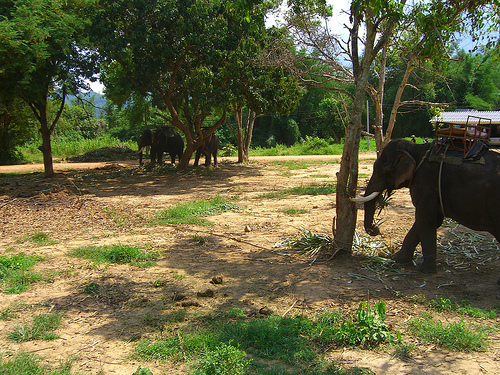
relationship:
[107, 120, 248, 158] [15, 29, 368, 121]
elephants under trees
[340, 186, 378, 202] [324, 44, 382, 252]
tusks near tree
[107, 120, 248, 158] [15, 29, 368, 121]
elephants near trees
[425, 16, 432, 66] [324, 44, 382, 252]
leaves on tree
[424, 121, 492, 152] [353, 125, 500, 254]
bench on elephant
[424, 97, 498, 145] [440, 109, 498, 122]
building has roof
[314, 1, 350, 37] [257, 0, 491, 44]
clouds in sky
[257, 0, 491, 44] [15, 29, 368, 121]
sky through trees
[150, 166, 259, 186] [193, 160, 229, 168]
shade under feet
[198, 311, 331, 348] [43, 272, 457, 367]
grass on ground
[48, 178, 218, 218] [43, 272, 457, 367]
dirt on ground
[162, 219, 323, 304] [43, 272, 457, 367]
shadow on ground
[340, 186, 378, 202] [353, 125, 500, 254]
tusks on elephant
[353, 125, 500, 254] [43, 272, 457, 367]
elephant on ground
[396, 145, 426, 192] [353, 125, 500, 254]
ear of elephant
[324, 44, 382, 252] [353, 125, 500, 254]
tree by elephant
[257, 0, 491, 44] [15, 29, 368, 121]
sky above trees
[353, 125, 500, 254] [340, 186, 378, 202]
elephant has tusks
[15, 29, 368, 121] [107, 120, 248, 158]
trees and elephants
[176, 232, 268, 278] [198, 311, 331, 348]
sand on grass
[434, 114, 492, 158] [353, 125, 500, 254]
bench on elephant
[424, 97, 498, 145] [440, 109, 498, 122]
barn with roof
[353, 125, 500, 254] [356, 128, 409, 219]
elephant has head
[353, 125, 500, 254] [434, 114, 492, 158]
elephant wearing bench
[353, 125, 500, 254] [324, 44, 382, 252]
elephant by tree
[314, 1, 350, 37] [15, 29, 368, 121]
clouds behind trees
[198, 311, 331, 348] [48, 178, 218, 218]
grass in dirt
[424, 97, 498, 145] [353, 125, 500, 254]
building near elephant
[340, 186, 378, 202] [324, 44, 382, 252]
tusks against tree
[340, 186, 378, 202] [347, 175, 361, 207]
tusks has mark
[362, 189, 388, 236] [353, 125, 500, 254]
trunk on elephant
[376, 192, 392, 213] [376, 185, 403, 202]
leaves in mouth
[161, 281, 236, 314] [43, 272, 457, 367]
droppings on ground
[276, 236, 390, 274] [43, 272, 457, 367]
leaves on ground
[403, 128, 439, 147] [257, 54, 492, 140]
people in background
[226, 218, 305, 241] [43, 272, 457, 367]
rock on ground